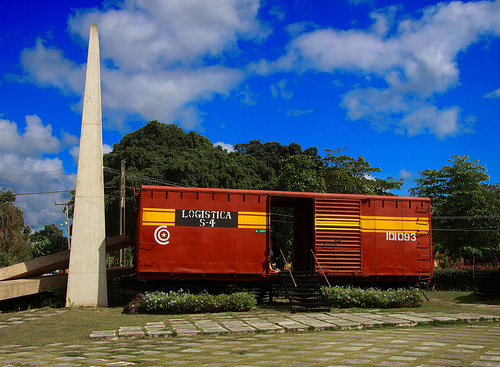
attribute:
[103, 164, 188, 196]
wires — electrical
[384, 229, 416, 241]
lettering — white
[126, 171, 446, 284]
train car — derailed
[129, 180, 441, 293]
train car — yellow, red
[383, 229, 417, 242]
101093 — white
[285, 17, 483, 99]
clouds — blue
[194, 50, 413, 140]
sky — blue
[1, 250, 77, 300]
slabs — cement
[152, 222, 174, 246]
target spot — white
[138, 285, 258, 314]
bushes — flowering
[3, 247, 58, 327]
wood — large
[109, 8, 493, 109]
clouds — white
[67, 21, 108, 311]
tower — white, long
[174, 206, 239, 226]
logo — logistica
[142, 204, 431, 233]
stripes — yellow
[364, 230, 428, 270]
background — red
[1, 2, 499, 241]
sky — blue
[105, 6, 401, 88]
clouds — white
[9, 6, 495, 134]
sky — blue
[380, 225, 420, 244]
101093 — written